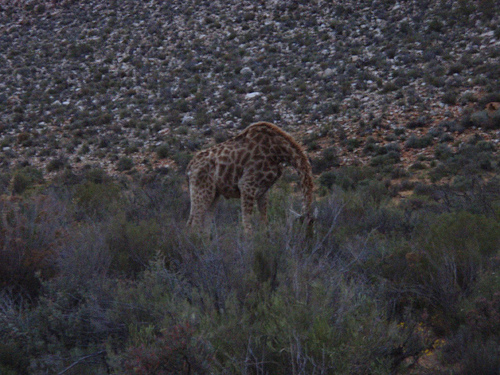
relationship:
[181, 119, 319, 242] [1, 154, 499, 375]
giraffe eating grass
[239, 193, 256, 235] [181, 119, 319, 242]
leg on giraffe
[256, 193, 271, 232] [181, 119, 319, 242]
leg on giraffe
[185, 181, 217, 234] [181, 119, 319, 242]
leg on giraffe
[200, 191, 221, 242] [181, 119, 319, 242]
leg on giraffe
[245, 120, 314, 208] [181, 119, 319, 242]
mane on giraffe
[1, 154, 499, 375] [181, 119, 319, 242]
grass in front of giraffe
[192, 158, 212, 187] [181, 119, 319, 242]
bump on giraffe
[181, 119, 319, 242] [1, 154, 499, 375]
giraffe in grass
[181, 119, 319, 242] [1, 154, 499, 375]
giraffe standing in grass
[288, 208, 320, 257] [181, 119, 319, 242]
head of giraffe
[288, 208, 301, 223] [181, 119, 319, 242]
ear of giraffe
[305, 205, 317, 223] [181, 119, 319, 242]
ear of giraffe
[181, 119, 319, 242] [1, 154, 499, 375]
giraffe grazing in grass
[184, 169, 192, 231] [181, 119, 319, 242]
tail of giraffe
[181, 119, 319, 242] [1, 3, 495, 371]
giraffe in field